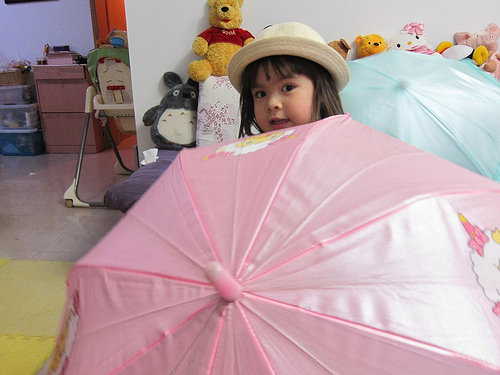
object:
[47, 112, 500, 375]
umbrella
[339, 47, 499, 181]
umbrella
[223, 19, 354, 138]
girl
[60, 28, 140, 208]
highchair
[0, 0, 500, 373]
background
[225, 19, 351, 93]
hat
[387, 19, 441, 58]
hello kitty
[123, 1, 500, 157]
wall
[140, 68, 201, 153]
bunny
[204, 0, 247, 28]
head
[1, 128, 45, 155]
container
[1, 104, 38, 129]
container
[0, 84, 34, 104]
container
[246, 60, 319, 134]
face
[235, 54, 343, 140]
hair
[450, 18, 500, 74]
animal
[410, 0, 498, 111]
top right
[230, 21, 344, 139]
head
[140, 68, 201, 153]
animal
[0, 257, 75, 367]
rug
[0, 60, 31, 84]
box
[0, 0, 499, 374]
room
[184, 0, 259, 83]
teddy bear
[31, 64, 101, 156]
dresser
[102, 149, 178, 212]
covering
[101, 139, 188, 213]
bed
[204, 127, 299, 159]
sheep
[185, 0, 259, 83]
animal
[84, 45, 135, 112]
seat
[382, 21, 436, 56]
animal